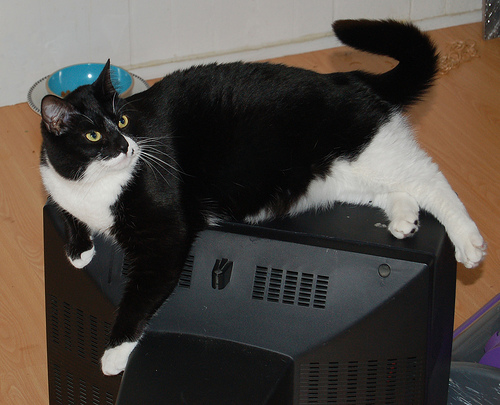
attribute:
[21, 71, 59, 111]
saucer — white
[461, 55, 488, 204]
table — brown, wooden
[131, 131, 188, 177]
wiskers — white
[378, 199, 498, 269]
back paws — white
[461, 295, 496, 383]
clothing — purple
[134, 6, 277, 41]
wall — white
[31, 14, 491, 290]
cat — black, looking, laying, laying down, looking around, white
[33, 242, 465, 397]
television — black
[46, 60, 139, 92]
bowl — blue, for food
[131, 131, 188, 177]
whiskers — white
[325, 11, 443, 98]
tail — black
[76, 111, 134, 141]
eyes — yellow, green, watching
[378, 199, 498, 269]
paws — white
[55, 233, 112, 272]
paw — the  left, the  front,  cat's, in the front, white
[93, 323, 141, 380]
paw —  cat's, the front, the right, white, in the front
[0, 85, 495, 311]
floor — brown, wood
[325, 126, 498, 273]
legs — white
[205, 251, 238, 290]
mount — for exterior antenna